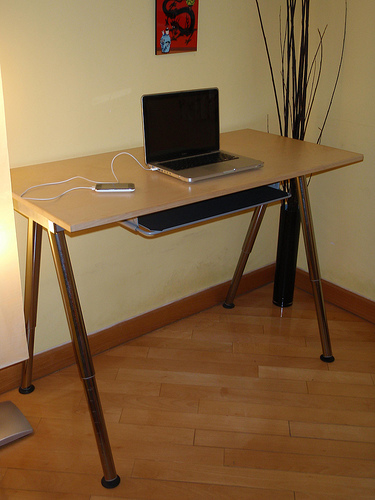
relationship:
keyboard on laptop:
[156, 150, 237, 172] [135, 86, 263, 182]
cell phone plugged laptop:
[96, 183, 135, 193] [131, 81, 269, 194]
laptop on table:
[135, 86, 263, 182] [10, 128, 363, 233]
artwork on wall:
[155, 1, 198, 54] [1, 0, 373, 392]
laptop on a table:
[135, 86, 263, 182] [8, 121, 351, 491]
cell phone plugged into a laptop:
[96, 183, 135, 193] [135, 86, 263, 182]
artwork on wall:
[155, 1, 198, 55] [3, 3, 368, 351]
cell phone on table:
[92, 181, 132, 192] [8, 121, 351, 491]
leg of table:
[221, 176, 274, 306] [9, 119, 371, 397]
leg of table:
[290, 176, 346, 364] [9, 119, 371, 397]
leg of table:
[13, 215, 41, 392] [9, 119, 371, 397]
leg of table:
[40, 224, 129, 488] [9, 119, 371, 397]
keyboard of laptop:
[159, 150, 239, 171] [135, 86, 263, 182]